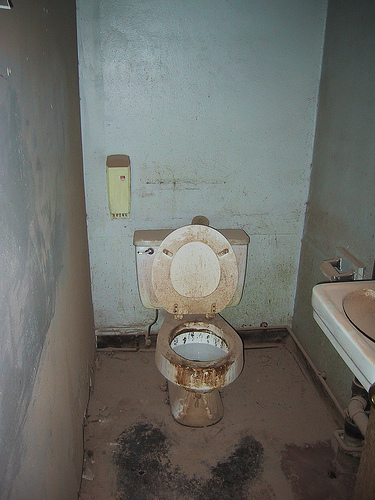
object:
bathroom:
[0, 0, 375, 498]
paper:
[319, 261, 342, 285]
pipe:
[349, 403, 359, 427]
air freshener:
[105, 154, 133, 219]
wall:
[0, 2, 375, 499]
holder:
[316, 244, 365, 281]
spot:
[113, 424, 265, 499]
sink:
[310, 278, 375, 389]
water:
[171, 341, 227, 362]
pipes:
[347, 393, 369, 446]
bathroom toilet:
[132, 217, 251, 427]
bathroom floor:
[81, 343, 357, 497]